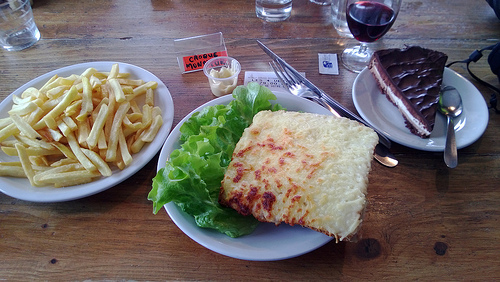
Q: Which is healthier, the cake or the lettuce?
A: The lettuce is healthier than the cake.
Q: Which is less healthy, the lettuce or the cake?
A: The cake is less healthy than the lettuce.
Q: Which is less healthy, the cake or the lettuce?
A: The cake is less healthy than the lettuce.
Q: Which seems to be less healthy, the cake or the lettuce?
A: The cake is less healthy than the lettuce.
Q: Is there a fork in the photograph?
A: Yes, there is a fork.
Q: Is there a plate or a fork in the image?
A: Yes, there is a fork.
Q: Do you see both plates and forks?
A: Yes, there are both a fork and a plate.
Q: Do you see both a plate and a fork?
A: Yes, there are both a fork and a plate.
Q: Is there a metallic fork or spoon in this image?
A: Yes, there is a metal fork.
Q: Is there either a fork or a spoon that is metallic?
A: Yes, the fork is metallic.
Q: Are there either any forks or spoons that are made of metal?
A: Yes, the fork is made of metal.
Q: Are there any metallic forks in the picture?
A: Yes, there is a metal fork.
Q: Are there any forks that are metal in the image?
A: Yes, there is a metal fork.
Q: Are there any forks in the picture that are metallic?
A: Yes, there is a fork that is metallic.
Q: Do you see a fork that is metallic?
A: Yes, there is a fork that is metallic.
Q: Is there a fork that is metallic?
A: Yes, there is a fork that is metallic.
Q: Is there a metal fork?
A: Yes, there is a fork that is made of metal.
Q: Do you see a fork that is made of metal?
A: Yes, there is a fork that is made of metal.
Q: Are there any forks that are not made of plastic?
A: Yes, there is a fork that is made of metal.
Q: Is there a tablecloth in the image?
A: No, there are no tablecloths.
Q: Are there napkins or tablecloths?
A: No, there are no tablecloths or napkins.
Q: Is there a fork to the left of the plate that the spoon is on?
A: Yes, there is a fork to the left of the plate.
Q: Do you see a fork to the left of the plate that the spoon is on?
A: Yes, there is a fork to the left of the plate.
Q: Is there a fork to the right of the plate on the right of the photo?
A: No, the fork is to the left of the plate.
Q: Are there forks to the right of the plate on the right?
A: No, the fork is to the left of the plate.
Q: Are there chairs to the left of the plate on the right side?
A: No, there is a fork to the left of the plate.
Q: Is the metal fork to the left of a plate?
A: Yes, the fork is to the left of a plate.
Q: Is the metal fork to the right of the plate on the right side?
A: No, the fork is to the left of the plate.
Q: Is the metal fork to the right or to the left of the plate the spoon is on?
A: The fork is to the left of the plate.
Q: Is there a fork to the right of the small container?
A: Yes, there is a fork to the right of the container.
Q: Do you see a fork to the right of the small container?
A: Yes, there is a fork to the right of the container.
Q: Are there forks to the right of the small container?
A: Yes, there is a fork to the right of the container.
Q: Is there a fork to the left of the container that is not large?
A: No, the fork is to the right of the container.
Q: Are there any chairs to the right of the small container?
A: No, there is a fork to the right of the container.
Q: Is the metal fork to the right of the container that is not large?
A: Yes, the fork is to the right of the container.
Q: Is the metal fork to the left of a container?
A: No, the fork is to the right of a container.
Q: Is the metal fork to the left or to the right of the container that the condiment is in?
A: The fork is to the right of the container.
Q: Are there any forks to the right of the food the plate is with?
A: Yes, there is a fork to the right of the food.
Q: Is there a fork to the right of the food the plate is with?
A: Yes, there is a fork to the right of the food.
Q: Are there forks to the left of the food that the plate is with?
A: No, the fork is to the right of the food.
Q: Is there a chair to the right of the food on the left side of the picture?
A: No, there is a fork to the right of the food.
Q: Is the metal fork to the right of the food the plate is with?
A: Yes, the fork is to the right of the food.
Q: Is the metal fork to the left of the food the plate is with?
A: No, the fork is to the right of the food.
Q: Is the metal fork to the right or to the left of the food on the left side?
A: The fork is to the right of the food.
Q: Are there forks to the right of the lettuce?
A: Yes, there is a fork to the right of the lettuce.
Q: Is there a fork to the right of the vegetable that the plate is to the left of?
A: Yes, there is a fork to the right of the lettuce.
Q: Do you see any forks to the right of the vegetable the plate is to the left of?
A: Yes, there is a fork to the right of the lettuce.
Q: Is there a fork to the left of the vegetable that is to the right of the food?
A: No, the fork is to the right of the lettuce.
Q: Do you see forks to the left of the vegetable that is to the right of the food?
A: No, the fork is to the right of the lettuce.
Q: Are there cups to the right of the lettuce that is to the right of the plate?
A: No, there is a fork to the right of the lettuce.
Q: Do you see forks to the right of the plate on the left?
A: Yes, there is a fork to the right of the plate.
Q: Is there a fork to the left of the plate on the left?
A: No, the fork is to the right of the plate.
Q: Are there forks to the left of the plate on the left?
A: No, the fork is to the right of the plate.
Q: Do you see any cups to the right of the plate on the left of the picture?
A: No, there is a fork to the right of the plate.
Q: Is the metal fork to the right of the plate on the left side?
A: Yes, the fork is to the right of the plate.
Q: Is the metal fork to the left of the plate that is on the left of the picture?
A: No, the fork is to the right of the plate.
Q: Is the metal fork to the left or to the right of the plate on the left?
A: The fork is to the right of the plate.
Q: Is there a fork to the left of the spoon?
A: Yes, there is a fork to the left of the spoon.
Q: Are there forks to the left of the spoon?
A: Yes, there is a fork to the left of the spoon.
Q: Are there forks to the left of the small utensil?
A: Yes, there is a fork to the left of the spoon.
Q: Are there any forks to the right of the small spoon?
A: No, the fork is to the left of the spoon.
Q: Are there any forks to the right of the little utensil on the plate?
A: No, the fork is to the left of the spoon.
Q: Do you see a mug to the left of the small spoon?
A: No, there is a fork to the left of the spoon.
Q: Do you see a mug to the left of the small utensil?
A: No, there is a fork to the left of the spoon.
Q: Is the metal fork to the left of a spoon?
A: Yes, the fork is to the left of a spoon.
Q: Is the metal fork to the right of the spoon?
A: No, the fork is to the left of the spoon.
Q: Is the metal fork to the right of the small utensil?
A: No, the fork is to the left of the spoon.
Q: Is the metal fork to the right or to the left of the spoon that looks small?
A: The fork is to the left of the spoon.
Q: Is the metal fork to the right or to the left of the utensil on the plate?
A: The fork is to the left of the spoon.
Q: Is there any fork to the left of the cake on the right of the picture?
A: Yes, there is a fork to the left of the cake.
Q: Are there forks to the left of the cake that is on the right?
A: Yes, there is a fork to the left of the cake.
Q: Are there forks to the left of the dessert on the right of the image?
A: Yes, there is a fork to the left of the cake.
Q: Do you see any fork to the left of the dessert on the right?
A: Yes, there is a fork to the left of the cake.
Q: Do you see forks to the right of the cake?
A: No, the fork is to the left of the cake.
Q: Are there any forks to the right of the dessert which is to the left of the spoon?
A: No, the fork is to the left of the cake.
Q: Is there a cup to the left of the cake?
A: No, there is a fork to the left of the cake.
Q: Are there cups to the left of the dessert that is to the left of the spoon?
A: No, there is a fork to the left of the cake.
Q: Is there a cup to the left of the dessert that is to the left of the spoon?
A: No, there is a fork to the left of the cake.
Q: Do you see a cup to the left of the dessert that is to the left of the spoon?
A: No, there is a fork to the left of the cake.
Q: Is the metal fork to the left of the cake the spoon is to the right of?
A: Yes, the fork is to the left of the cake.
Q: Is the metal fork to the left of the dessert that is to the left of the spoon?
A: Yes, the fork is to the left of the cake.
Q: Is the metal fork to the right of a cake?
A: No, the fork is to the left of a cake.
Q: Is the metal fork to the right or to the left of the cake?
A: The fork is to the left of the cake.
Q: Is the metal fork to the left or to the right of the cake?
A: The fork is to the left of the cake.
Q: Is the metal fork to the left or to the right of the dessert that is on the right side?
A: The fork is to the left of the cake.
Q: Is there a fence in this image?
A: No, there are no fences.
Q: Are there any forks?
A: Yes, there is a fork.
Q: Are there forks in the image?
A: Yes, there is a fork.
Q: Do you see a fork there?
A: Yes, there is a fork.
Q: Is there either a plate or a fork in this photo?
A: Yes, there is a fork.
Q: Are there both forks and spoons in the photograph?
A: Yes, there are both a fork and a spoon.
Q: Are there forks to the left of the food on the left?
A: No, the fork is to the right of the food.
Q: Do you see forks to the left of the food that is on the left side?
A: No, the fork is to the right of the food.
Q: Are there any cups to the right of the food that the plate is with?
A: No, there is a fork to the right of the food.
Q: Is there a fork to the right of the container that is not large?
A: Yes, there is a fork to the right of the container.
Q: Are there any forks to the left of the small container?
A: No, the fork is to the right of the container.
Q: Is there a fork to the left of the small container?
A: No, the fork is to the right of the container.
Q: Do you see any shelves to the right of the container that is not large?
A: No, there is a fork to the right of the container.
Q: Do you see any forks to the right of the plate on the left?
A: Yes, there is a fork to the right of the plate.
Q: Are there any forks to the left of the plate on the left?
A: No, the fork is to the right of the plate.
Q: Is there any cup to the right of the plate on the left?
A: No, there is a fork to the right of the plate.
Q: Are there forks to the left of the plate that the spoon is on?
A: Yes, there is a fork to the left of the plate.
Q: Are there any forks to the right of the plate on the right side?
A: No, the fork is to the left of the plate.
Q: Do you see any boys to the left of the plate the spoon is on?
A: No, there is a fork to the left of the plate.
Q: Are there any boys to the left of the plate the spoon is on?
A: No, there is a fork to the left of the plate.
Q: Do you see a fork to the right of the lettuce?
A: Yes, there is a fork to the right of the lettuce.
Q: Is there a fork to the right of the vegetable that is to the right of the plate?
A: Yes, there is a fork to the right of the lettuce.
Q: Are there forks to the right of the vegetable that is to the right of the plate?
A: Yes, there is a fork to the right of the lettuce.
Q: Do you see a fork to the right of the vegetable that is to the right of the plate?
A: Yes, there is a fork to the right of the lettuce.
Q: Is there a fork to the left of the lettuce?
A: No, the fork is to the right of the lettuce.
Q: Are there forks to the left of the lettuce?
A: No, the fork is to the right of the lettuce.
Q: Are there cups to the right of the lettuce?
A: No, there is a fork to the right of the lettuce.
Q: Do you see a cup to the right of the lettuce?
A: No, there is a fork to the right of the lettuce.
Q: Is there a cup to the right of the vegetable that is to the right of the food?
A: No, there is a fork to the right of the lettuce.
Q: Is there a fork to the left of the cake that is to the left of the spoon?
A: Yes, there is a fork to the left of the cake.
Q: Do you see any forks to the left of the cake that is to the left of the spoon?
A: Yes, there is a fork to the left of the cake.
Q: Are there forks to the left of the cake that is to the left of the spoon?
A: Yes, there is a fork to the left of the cake.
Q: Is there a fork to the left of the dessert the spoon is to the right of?
A: Yes, there is a fork to the left of the cake.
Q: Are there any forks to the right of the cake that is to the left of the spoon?
A: No, the fork is to the left of the cake.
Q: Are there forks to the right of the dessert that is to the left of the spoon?
A: No, the fork is to the left of the cake.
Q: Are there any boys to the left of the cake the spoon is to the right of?
A: No, there is a fork to the left of the cake.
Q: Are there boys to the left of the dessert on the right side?
A: No, there is a fork to the left of the cake.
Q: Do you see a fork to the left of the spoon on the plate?
A: Yes, there is a fork to the left of the spoon.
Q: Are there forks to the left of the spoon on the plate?
A: Yes, there is a fork to the left of the spoon.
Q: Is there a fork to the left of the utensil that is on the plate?
A: Yes, there is a fork to the left of the spoon.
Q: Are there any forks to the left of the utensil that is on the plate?
A: Yes, there is a fork to the left of the spoon.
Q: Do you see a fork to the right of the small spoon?
A: No, the fork is to the left of the spoon.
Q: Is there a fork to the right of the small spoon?
A: No, the fork is to the left of the spoon.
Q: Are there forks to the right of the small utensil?
A: No, the fork is to the left of the spoon.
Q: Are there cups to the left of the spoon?
A: No, there is a fork to the left of the spoon.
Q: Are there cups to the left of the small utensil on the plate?
A: No, there is a fork to the left of the spoon.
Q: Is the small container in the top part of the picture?
A: Yes, the container is in the top of the image.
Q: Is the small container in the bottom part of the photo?
A: No, the container is in the top of the image.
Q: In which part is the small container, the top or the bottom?
A: The container is in the top of the image.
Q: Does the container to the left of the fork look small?
A: Yes, the container is small.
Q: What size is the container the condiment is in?
A: The container is small.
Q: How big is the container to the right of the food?
A: The container is small.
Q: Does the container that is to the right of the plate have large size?
A: No, the container is small.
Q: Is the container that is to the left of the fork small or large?
A: The container is small.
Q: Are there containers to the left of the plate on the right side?
A: Yes, there is a container to the left of the plate.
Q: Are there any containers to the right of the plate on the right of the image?
A: No, the container is to the left of the plate.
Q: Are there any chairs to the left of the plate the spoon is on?
A: No, there is a container to the left of the plate.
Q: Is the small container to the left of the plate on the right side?
A: Yes, the container is to the left of the plate.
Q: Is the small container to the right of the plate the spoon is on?
A: No, the container is to the left of the plate.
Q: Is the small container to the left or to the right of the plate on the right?
A: The container is to the left of the plate.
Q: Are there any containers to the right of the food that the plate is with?
A: Yes, there is a container to the right of the food.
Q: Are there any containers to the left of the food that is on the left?
A: No, the container is to the right of the food.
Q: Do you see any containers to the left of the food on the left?
A: No, the container is to the right of the food.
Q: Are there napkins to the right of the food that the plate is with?
A: No, there is a container to the right of the food.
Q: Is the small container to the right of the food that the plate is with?
A: Yes, the container is to the right of the food.